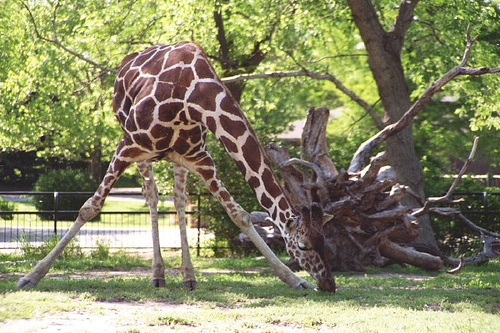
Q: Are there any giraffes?
A: Yes, there is a giraffe.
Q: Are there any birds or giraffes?
A: Yes, there is a giraffe.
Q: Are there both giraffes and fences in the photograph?
A: Yes, there are both a giraffe and a fence.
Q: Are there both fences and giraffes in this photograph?
A: Yes, there are both a giraffe and a fence.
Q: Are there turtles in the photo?
A: No, there are no turtles.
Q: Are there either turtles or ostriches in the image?
A: No, there are no turtles or ostriches.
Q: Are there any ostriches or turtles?
A: No, there are no turtles or ostriches.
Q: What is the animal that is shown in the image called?
A: The animal is a giraffe.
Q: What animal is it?
A: The animal is a giraffe.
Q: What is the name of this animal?
A: This is a giraffe.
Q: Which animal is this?
A: This is a giraffe.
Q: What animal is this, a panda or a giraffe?
A: This is a giraffe.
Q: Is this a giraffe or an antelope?
A: This is a giraffe.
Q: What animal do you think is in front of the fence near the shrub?
A: The giraffe is in front of the fence.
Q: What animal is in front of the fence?
A: The giraffe is in front of the fence.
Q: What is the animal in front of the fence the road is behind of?
A: The animal is a giraffe.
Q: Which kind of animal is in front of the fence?
A: The animal is a giraffe.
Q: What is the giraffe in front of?
A: The giraffe is in front of the fence.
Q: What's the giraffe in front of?
A: The giraffe is in front of the fence.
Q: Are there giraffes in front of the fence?
A: Yes, there is a giraffe in front of the fence.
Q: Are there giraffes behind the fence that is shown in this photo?
A: No, the giraffe is in front of the fence.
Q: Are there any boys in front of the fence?
A: No, there is a giraffe in front of the fence.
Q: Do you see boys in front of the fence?
A: No, there is a giraffe in front of the fence.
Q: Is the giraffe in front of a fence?
A: Yes, the giraffe is in front of a fence.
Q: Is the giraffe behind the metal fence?
A: No, the giraffe is in front of the fence.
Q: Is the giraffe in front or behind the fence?
A: The giraffe is in front of the fence.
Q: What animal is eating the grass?
A: The giraffe is eating the grass.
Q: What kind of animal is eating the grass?
A: The animal is a giraffe.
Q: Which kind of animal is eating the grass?
A: The animal is a giraffe.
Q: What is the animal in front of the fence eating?
A: The giraffe is eating grass.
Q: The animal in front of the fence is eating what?
A: The giraffe is eating grass.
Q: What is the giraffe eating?
A: The giraffe is eating grass.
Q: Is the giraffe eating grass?
A: Yes, the giraffe is eating grass.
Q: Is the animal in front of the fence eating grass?
A: Yes, the giraffe is eating grass.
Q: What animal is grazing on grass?
A: The giraffe is grazing on grass.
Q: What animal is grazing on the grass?
A: The giraffe is grazing on grass.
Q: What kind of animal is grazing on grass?
A: The animal is a giraffe.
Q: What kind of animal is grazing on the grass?
A: The animal is a giraffe.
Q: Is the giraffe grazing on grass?
A: Yes, the giraffe is grazing on grass.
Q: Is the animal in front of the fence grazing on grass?
A: Yes, the giraffe is grazing on grass.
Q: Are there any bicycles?
A: No, there are no bicycles.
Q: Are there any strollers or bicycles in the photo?
A: No, there are no bicycles or strollers.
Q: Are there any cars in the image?
A: No, there are no cars.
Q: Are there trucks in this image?
A: No, there are no trucks.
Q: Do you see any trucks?
A: No, there are no trucks.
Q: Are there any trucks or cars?
A: No, there are no trucks or cars.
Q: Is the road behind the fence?
A: Yes, the road is behind the fence.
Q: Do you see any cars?
A: No, there are no cars.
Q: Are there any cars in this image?
A: No, there are no cars.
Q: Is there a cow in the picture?
A: No, there are no cows.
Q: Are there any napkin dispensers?
A: No, there are no napkin dispensers.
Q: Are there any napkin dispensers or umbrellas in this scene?
A: No, there are no napkin dispensers or umbrellas.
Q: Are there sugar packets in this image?
A: No, there are no sugar packets.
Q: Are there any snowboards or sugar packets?
A: No, there are no sugar packets or snowboards.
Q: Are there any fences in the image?
A: Yes, there is a fence.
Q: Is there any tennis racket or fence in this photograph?
A: Yes, there is a fence.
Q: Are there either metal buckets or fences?
A: Yes, there is a metal fence.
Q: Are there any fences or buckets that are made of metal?
A: Yes, the fence is made of metal.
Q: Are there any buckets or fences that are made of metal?
A: Yes, the fence is made of metal.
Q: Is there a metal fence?
A: Yes, there is a metal fence.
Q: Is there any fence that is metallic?
A: Yes, there is a fence that is metallic.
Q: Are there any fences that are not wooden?
A: Yes, there is a metallic fence.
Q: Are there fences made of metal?
A: Yes, there is a fence that is made of metal.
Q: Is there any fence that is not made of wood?
A: Yes, there is a fence that is made of metal.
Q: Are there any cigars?
A: No, there are no cigars.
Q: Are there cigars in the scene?
A: No, there are no cigars.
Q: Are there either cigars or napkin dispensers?
A: No, there are no cigars or napkin dispensers.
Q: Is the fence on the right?
A: No, the fence is on the left of the image.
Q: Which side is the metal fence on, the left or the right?
A: The fence is on the left of the image.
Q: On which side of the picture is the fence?
A: The fence is on the left of the image.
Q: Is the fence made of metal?
A: Yes, the fence is made of metal.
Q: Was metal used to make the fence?
A: Yes, the fence is made of metal.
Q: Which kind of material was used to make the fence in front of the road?
A: The fence is made of metal.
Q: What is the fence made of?
A: The fence is made of metal.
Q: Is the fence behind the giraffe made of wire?
A: No, the fence is made of metal.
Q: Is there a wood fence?
A: No, there is a fence but it is made of metal.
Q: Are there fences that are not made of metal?
A: No, there is a fence but it is made of metal.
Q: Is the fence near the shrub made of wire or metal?
A: The fence is made of metal.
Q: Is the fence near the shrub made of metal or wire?
A: The fence is made of metal.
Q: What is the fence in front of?
A: The fence is in front of the road.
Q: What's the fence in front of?
A: The fence is in front of the road.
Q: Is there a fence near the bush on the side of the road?
A: Yes, there is a fence near the bush.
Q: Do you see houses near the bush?
A: No, there is a fence near the bush.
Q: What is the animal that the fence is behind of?
A: The animal is a giraffe.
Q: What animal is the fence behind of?
A: The fence is behind the giraffe.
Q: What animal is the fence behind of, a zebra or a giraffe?
A: The fence is behind a giraffe.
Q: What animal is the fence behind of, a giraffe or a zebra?
A: The fence is behind a giraffe.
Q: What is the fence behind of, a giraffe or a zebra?
A: The fence is behind a giraffe.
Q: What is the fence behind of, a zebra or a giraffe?
A: The fence is behind a giraffe.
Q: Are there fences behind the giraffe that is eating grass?
A: Yes, there is a fence behind the giraffe.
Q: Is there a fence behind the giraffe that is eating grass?
A: Yes, there is a fence behind the giraffe.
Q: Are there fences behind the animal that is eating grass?
A: Yes, there is a fence behind the giraffe.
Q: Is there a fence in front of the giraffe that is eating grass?
A: No, the fence is behind the giraffe.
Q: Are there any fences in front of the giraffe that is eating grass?
A: No, the fence is behind the giraffe.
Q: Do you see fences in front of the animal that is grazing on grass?
A: No, the fence is behind the giraffe.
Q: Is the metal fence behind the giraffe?
A: Yes, the fence is behind the giraffe.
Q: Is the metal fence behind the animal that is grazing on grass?
A: Yes, the fence is behind the giraffe.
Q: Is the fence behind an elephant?
A: No, the fence is behind the giraffe.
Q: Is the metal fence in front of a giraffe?
A: No, the fence is behind a giraffe.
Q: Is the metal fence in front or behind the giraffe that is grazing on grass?
A: The fence is behind the giraffe.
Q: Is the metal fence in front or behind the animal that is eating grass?
A: The fence is behind the giraffe.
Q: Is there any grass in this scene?
A: Yes, there is grass.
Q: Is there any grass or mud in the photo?
A: Yes, there is grass.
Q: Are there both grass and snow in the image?
A: No, there is grass but no snow.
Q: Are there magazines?
A: No, there are no magazines.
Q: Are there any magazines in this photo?
A: No, there are no magazines.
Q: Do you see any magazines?
A: No, there are no magazines.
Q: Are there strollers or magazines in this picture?
A: No, there are no magazines or strollers.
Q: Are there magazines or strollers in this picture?
A: No, there are no magazines or strollers.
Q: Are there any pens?
A: No, there are no pens.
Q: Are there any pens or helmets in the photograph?
A: No, there are no pens or helmets.